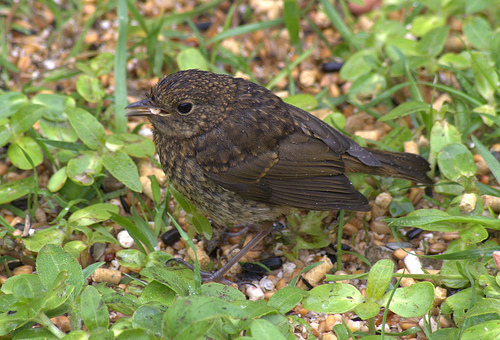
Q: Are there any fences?
A: No, there are no fences.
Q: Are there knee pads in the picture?
A: No, there are no knee pads.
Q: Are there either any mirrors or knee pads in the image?
A: No, there are no knee pads or mirrors.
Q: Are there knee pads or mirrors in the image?
A: No, there are no knee pads or mirrors.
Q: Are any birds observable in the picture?
A: Yes, there is a bird.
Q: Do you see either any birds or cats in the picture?
A: Yes, there is a bird.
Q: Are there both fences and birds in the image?
A: No, there is a bird but no fences.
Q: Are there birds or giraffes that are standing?
A: Yes, the bird is standing.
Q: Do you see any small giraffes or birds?
A: Yes, there is a small bird.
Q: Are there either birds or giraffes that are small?
A: Yes, the bird is small.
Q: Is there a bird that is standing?
A: Yes, there is a bird that is standing.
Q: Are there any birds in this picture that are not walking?
A: Yes, there is a bird that is standing.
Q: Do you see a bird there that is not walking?
A: Yes, there is a bird that is standing .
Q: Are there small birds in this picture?
A: Yes, there is a small bird.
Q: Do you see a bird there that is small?
A: Yes, there is a bird that is small.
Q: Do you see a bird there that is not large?
A: Yes, there is a small bird.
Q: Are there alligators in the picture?
A: No, there are no alligators.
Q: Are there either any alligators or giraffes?
A: No, there are no alligators or giraffes.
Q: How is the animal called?
A: The animal is a bird.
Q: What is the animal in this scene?
A: The animal is a bird.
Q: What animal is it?
A: The animal is a bird.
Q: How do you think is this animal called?
A: This is a bird.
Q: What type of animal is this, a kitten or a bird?
A: This is a bird.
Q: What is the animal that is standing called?
A: The animal is a bird.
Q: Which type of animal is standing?
A: The animal is a bird.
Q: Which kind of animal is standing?
A: The animal is a bird.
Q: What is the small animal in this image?
A: The animal is a bird.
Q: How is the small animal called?
A: The animal is a bird.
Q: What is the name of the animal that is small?
A: The animal is a bird.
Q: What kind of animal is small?
A: The animal is a bird.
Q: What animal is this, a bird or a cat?
A: This is a bird.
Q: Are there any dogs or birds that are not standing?
A: No, there is a bird but it is standing.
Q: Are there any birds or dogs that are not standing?
A: No, there is a bird but it is standing.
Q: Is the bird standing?
A: Yes, the bird is standing.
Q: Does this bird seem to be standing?
A: Yes, the bird is standing.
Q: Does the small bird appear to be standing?
A: Yes, the bird is standing.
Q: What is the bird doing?
A: The bird is standing.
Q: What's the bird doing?
A: The bird is standing.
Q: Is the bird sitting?
A: No, the bird is standing.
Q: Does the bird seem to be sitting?
A: No, the bird is standing.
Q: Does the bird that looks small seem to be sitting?
A: No, the bird is standing.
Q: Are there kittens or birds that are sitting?
A: No, there is a bird but it is standing.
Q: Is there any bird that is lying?
A: No, there is a bird but it is standing.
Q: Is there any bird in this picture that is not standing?
A: No, there is a bird but it is standing.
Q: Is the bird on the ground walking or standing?
A: The bird is standing.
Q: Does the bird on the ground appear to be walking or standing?
A: The bird is standing.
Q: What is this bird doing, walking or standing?
A: The bird is standing.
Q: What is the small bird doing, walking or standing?
A: The bird is standing.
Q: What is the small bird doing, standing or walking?
A: The bird is standing.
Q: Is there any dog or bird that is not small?
A: No, there is a bird but it is small.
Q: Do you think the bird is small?
A: Yes, the bird is small.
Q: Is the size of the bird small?
A: Yes, the bird is small.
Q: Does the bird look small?
A: Yes, the bird is small.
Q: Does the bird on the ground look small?
A: Yes, the bird is small.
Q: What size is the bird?
A: The bird is small.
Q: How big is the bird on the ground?
A: The bird is small.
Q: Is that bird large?
A: No, the bird is small.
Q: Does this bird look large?
A: No, the bird is small.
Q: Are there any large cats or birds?
A: No, there is a bird but it is small.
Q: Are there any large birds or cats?
A: No, there is a bird but it is small.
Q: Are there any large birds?
A: No, there is a bird but it is small.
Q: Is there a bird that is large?
A: No, there is a bird but it is small.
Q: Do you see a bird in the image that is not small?
A: No, there is a bird but it is small.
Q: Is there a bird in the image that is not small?
A: No, there is a bird but it is small.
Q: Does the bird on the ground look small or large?
A: The bird is small.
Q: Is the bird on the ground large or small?
A: The bird is small.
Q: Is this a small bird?
A: Yes, this is a small bird.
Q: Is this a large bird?
A: No, this is a small bird.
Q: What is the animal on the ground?
A: The animal is a bird.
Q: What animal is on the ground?
A: The animal is a bird.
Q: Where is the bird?
A: The bird is on the ground.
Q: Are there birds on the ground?
A: Yes, there is a bird on the ground.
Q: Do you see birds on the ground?
A: Yes, there is a bird on the ground.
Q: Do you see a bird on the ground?
A: Yes, there is a bird on the ground.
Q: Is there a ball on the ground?
A: No, there is a bird on the ground.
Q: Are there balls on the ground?
A: No, there is a bird on the ground.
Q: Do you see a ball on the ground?
A: No, there is a bird on the ground.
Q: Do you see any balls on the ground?
A: No, there is a bird on the ground.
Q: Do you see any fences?
A: No, there are no fences.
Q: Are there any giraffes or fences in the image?
A: No, there are no fences or giraffes.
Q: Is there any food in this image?
A: Yes, there is food.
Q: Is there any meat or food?
A: Yes, there is food.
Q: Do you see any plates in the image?
A: No, there are no plates.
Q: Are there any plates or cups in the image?
A: No, there are no plates or cups.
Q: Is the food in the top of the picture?
A: No, the food is in the bottom of the image.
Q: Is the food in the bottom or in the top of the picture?
A: The food is in the bottom of the image.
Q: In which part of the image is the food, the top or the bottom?
A: The food is in the bottom of the image.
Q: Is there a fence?
A: No, there are no fences.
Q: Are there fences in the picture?
A: No, there are no fences.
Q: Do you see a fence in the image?
A: No, there are no fences.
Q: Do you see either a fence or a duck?
A: No, there are no fences or ducks.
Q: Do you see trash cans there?
A: No, there are no trash cans.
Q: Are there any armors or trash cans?
A: No, there are no trash cans or armors.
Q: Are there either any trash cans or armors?
A: No, there are no trash cans or armors.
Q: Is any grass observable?
A: Yes, there is grass.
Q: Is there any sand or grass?
A: Yes, there is grass.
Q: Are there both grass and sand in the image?
A: No, there is grass but no sand.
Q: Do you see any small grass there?
A: Yes, there is small grass.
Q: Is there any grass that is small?
A: Yes, there is small grass.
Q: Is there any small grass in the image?
A: Yes, there is small grass.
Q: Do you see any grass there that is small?
A: Yes, there is grass that is small.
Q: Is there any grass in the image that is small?
A: Yes, there is grass that is small.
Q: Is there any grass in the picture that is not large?
A: Yes, there is small grass.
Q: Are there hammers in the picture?
A: No, there are no hammers.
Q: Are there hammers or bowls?
A: No, there are no hammers or bowls.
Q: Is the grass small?
A: Yes, the grass is small.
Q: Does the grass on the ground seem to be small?
A: Yes, the grass is small.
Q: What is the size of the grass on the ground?
A: The grass is small.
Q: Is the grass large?
A: No, the grass is small.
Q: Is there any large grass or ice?
A: No, there is grass but it is small.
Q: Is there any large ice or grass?
A: No, there is grass but it is small.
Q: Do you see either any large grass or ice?
A: No, there is grass but it is small.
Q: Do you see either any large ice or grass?
A: No, there is grass but it is small.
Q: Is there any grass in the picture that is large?
A: No, there is grass but it is small.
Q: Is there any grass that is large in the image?
A: No, there is grass but it is small.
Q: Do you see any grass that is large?
A: No, there is grass but it is small.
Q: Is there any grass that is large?
A: No, there is grass but it is small.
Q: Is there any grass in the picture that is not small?
A: No, there is grass but it is small.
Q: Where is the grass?
A: The grass is on the ground.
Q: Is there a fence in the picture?
A: No, there are no fences.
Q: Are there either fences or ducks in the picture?
A: No, there are no fences or ducks.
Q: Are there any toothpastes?
A: No, there are no toothpastes.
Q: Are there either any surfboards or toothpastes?
A: No, there are no toothpastes or surfboards.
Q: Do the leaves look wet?
A: Yes, the leaves are wet.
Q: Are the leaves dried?
A: No, the leaves are wet.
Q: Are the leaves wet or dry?
A: The leaves are wet.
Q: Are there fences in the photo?
A: No, there are no fences.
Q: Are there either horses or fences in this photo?
A: No, there are no fences or horses.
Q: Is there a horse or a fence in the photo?
A: No, there are no fences or horses.